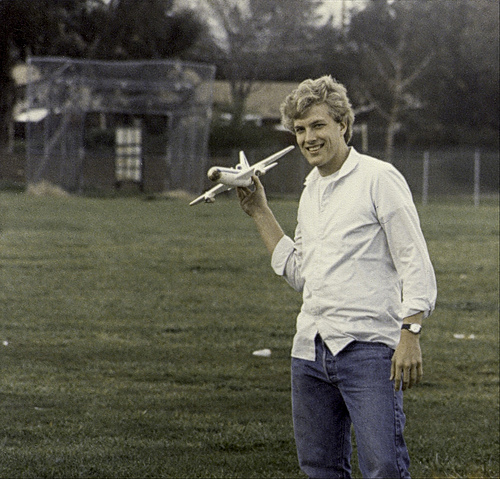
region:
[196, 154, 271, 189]
this is a toy airplane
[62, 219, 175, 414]
this is the grass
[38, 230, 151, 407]
the grass is long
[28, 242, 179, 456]
the grass is green in color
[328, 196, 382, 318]
the shirt is white in color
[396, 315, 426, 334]
this is a wrist watch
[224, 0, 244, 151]
this is a tree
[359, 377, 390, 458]
a pair of blue trousers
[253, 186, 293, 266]
the man's arm is raised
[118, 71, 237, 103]
this is a house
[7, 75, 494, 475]
the photo was taken outdoors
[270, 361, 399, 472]
the jeans are blue in color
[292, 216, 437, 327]
the man has a white shirt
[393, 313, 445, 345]
the man has a watch on his right hand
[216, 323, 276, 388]
there is white trash on the field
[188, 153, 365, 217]
the man is holding the plane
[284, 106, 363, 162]
the man is smiling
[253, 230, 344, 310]
the mans shirt hands are folded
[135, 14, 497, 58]
there are trees in the background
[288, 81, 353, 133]
his hair is brown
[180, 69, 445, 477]
The man holds an airplane.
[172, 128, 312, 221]
The airplane is a model.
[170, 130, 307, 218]
The airplane is white.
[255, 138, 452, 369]
The man's shirt is white.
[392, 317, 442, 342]
The man wears a watch.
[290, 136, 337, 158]
The man is smiling.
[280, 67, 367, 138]
The man has blonde hair.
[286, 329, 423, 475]
The man wears jeans.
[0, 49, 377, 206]
A building is in the background.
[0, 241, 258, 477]
The ground is covered with grass.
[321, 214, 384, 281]
part of a white shirt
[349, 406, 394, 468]
part of a blue jeans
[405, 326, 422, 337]
part of a wrist watch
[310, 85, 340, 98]
hair of a man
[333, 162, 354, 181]
collar of the shirt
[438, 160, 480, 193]
part of a fence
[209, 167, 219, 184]
tip of the plane model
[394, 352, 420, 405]
left hand of the man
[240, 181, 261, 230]
right hand of the man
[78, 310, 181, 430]
part of some grass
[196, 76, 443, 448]
One person is seen.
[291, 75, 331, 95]
Hair is blonde color.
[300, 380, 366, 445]
Pant is blue color.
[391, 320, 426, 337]
Man is wearing watch in left.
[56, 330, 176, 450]
Grass is green color.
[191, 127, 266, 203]
Man is holding plane doll in hand.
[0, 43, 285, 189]
Building is behind the man.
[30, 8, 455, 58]
Trees are behind the man.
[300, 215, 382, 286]
Man is in white shirt.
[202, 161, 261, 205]
Plane is white color.